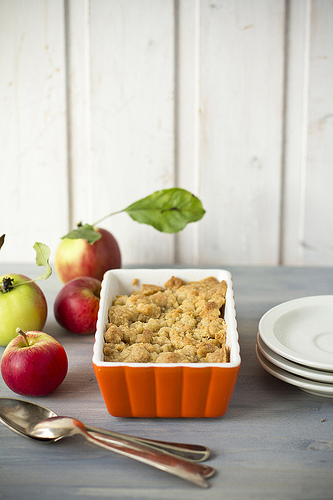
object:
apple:
[54, 227, 121, 284]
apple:
[54, 277, 101, 336]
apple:
[0, 273, 48, 346]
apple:
[0, 330, 68, 397]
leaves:
[123, 186, 207, 234]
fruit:
[53, 276, 101, 335]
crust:
[103, 275, 230, 362]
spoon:
[25, 416, 215, 490]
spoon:
[0, 397, 210, 463]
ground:
[0, 259, 333, 499]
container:
[91, 267, 241, 418]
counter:
[0, 260, 333, 499]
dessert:
[103, 275, 230, 364]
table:
[0, 259, 331, 500]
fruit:
[0, 273, 48, 348]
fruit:
[0, 329, 69, 397]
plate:
[257, 293, 333, 370]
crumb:
[132, 278, 138, 286]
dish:
[257, 293, 332, 371]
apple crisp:
[102, 275, 230, 362]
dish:
[254, 293, 333, 392]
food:
[102, 275, 230, 365]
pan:
[91, 267, 241, 418]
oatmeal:
[102, 275, 229, 363]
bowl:
[91, 267, 241, 418]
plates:
[256, 293, 333, 383]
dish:
[254, 293, 333, 384]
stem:
[92, 208, 125, 226]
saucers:
[254, 293, 332, 392]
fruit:
[54, 225, 121, 286]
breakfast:
[102, 276, 229, 363]